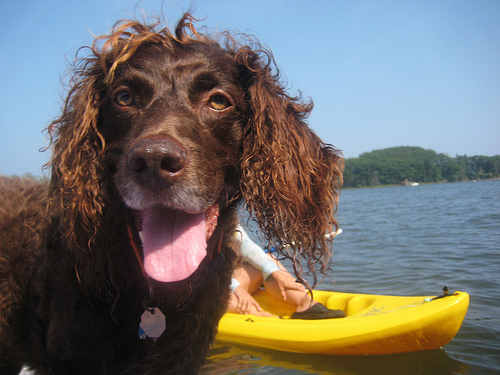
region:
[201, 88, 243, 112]
eye of the dog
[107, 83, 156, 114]
eye of the dog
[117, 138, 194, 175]
nose of the dog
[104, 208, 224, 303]
tongue of the dog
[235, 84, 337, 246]
ear of the dog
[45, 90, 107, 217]
ear of the dog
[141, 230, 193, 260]
the tongue is pink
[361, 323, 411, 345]
the raft is yellow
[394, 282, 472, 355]
raft in the water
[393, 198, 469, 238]
the water is calm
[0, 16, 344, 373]
Brown dog with curly fur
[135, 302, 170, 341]
Silver hexagon dog tag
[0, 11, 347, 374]
Dog with tongue sticking out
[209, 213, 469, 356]
Yellow canoe on water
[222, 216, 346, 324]
Woman sitting in yellow canoe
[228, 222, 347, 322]
Woman grabbing lower legs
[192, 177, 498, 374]
Large body of water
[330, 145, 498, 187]
Large trees in background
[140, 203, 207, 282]
Dog tongue sticking out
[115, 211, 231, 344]
Dog collar with tags attached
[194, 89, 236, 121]
right eye of dog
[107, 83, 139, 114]
left eye of dog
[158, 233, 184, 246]
middle of dogs tongue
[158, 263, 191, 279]
tip of dogs tongue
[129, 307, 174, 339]
silver symbol on chain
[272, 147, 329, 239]
dog ear on right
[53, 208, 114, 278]
dog ear on left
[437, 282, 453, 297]
handle on motor boat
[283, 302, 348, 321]
person wearing black shoes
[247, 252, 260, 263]
person wearing white shirt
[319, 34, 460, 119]
Sky is blue color.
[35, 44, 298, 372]
Dog is brown color.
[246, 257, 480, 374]
Boat is yellow color.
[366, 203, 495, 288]
Water is blue color.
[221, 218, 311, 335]
One person is sitting in boat.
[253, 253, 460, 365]
Boat is in water.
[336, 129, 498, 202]
Trees are behind the water.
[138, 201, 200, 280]
Tongue is pink color.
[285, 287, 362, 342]
Man is wearing black foot wear.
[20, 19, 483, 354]
Day time picture.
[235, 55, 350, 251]
furry black ear of dog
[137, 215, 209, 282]
orange tongue of dog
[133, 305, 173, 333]
silver collar of dog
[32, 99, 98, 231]
furry black ear of dgo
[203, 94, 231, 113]
black and yellow eye of dgo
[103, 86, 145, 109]
black and yellow eye of dog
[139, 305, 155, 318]
small metal loop on collar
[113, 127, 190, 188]
black nose of dog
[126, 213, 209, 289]
pink tongue in mouth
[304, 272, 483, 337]
yellow kayak in the water